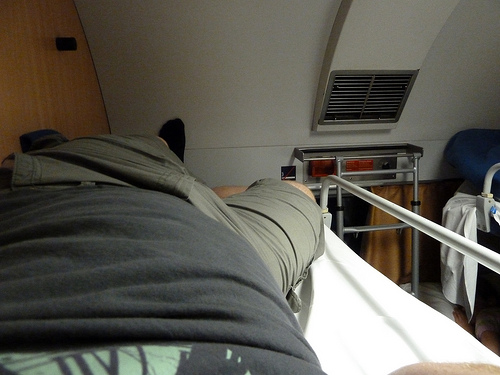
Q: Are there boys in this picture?
A: No, there are no boys.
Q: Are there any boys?
A: No, there are no boys.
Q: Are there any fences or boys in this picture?
A: No, there are no boys or fences.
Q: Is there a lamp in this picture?
A: No, there are no lamps.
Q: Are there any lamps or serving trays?
A: No, there are no lamps or serving trays.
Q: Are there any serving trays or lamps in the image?
A: No, there are no lamps or serving trays.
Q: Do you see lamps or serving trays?
A: No, there are no lamps or serving trays.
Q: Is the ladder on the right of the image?
A: Yes, the ladder is on the right of the image.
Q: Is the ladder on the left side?
A: No, the ladder is on the right of the image.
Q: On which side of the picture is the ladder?
A: The ladder is on the right of the image.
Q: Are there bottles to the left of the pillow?
A: No, there is a ladder to the left of the pillow.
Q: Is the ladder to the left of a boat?
A: No, the ladder is to the left of a pillow.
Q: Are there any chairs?
A: No, there are no chairs.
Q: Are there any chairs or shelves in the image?
A: No, there are no chairs or shelves.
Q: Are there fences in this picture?
A: No, there are no fences.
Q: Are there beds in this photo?
A: Yes, there is a bed.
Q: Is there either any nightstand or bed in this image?
A: Yes, there is a bed.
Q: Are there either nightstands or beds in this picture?
A: Yes, there is a bed.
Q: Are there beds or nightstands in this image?
A: Yes, there is a bed.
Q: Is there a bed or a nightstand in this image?
A: Yes, there is a bed.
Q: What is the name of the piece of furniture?
A: The piece of furniture is a bed.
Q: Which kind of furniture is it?
A: The piece of furniture is a bed.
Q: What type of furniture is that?
A: That is a bed.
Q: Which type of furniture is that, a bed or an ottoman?
A: That is a bed.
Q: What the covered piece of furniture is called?
A: The piece of furniture is a bed.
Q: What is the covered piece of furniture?
A: The piece of furniture is a bed.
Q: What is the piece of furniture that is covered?
A: The piece of furniture is a bed.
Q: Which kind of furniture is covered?
A: The furniture is a bed.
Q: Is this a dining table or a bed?
A: This is a bed.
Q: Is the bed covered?
A: Yes, the bed is covered.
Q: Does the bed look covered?
A: Yes, the bed is covered.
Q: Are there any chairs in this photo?
A: No, there are no chairs.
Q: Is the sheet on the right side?
A: Yes, the sheet is on the right of the image.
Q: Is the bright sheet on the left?
A: No, the sheet is on the right of the image.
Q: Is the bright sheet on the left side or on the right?
A: The bed sheet is on the right of the image.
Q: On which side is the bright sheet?
A: The bed sheet is on the right of the image.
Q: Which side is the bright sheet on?
A: The bed sheet is on the right of the image.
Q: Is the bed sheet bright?
A: Yes, the bed sheet is bright.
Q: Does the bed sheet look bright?
A: Yes, the bed sheet is bright.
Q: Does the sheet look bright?
A: Yes, the sheet is bright.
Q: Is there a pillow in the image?
A: Yes, there is a pillow.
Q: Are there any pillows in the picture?
A: Yes, there is a pillow.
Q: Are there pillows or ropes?
A: Yes, there is a pillow.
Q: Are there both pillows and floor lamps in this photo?
A: No, there is a pillow but no floor lamps.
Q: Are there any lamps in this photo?
A: No, there are no lamps.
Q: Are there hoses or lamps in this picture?
A: No, there are no lamps or hoses.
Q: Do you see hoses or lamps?
A: No, there are no lamps or hoses.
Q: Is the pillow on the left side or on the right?
A: The pillow is on the right of the image.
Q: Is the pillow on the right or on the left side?
A: The pillow is on the right of the image.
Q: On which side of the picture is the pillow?
A: The pillow is on the right of the image.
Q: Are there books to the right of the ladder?
A: No, there is a pillow to the right of the ladder.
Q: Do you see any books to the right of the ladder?
A: No, there is a pillow to the right of the ladder.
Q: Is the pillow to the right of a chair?
A: No, the pillow is to the right of a ladder.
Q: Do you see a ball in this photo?
A: No, there are no balls.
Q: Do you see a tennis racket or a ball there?
A: No, there are no balls or rackets.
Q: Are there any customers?
A: No, there are no customers.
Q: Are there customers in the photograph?
A: No, there are no customers.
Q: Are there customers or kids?
A: No, there are no customers or kids.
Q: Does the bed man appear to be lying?
A: Yes, the man is lying.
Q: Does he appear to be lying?
A: Yes, the man is lying.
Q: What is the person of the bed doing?
A: The man is lying.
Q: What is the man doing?
A: The man is lying.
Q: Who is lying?
A: The man is lying.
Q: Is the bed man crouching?
A: No, the man is lying.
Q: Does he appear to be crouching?
A: No, the man is lying.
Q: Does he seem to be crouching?
A: No, the man is lying.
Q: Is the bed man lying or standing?
A: The man is lying.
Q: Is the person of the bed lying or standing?
A: The man is lying.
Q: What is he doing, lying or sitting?
A: The man is lying.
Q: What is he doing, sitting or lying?
A: The man is lying.